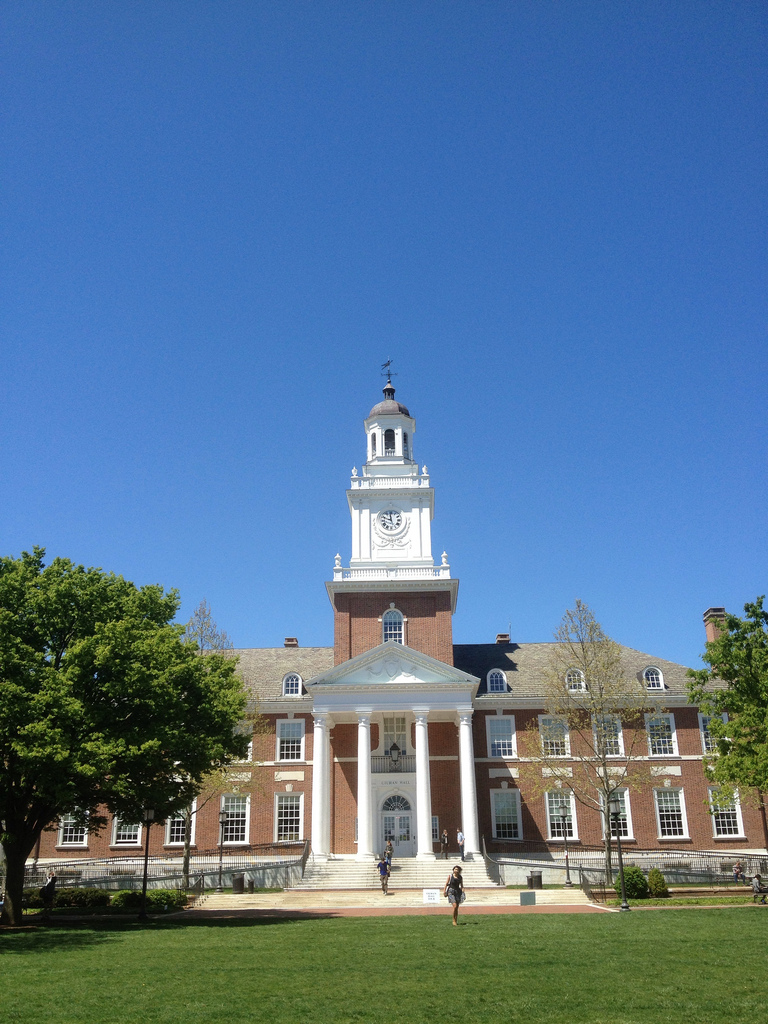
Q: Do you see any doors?
A: Yes, there is a door.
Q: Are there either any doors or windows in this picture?
A: Yes, there is a door.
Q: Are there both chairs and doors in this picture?
A: No, there is a door but no chairs.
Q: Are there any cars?
A: No, there are no cars.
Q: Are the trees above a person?
A: Yes, the trees are above a person.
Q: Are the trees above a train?
A: No, the trees are above a person.